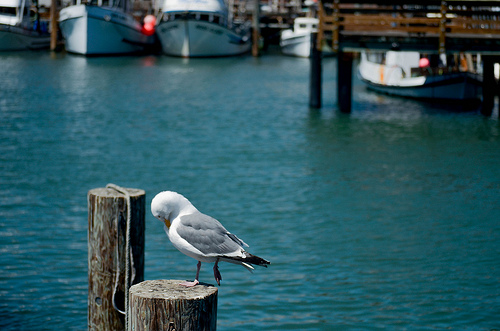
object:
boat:
[152, 0, 256, 59]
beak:
[163, 219, 171, 230]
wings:
[166, 212, 250, 256]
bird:
[148, 188, 272, 288]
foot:
[179, 260, 203, 287]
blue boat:
[56, 2, 154, 58]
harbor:
[0, 0, 500, 131]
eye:
[156, 215, 161, 219]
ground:
[352, 145, 394, 184]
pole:
[124, 278, 222, 331]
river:
[0, 51, 500, 331]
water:
[0, 53, 500, 331]